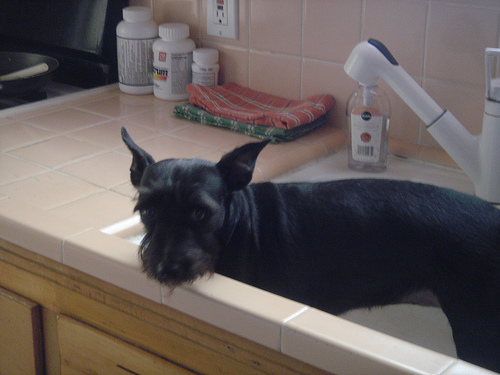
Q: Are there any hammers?
A: No, there are no hammers.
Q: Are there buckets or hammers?
A: No, there are no hammers or buckets.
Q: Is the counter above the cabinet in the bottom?
A: Yes, the counter is above the cabinet.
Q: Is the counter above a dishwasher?
A: No, the counter is above the cabinet.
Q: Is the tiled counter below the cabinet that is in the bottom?
A: No, the counter is above the cabinet.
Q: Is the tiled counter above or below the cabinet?
A: The counter is above the cabinet.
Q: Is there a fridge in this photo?
A: No, there are no refrigerators.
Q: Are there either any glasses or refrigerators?
A: No, there are no refrigerators or glasses.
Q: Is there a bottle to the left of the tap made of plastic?
A: Yes, there are bottles to the left of the faucet.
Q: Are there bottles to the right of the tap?
A: No, the bottles are to the left of the tap.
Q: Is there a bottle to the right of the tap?
A: No, the bottles are to the left of the tap.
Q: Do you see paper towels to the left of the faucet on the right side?
A: No, there are bottles to the left of the tap.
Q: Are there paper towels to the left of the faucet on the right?
A: No, there are bottles to the left of the tap.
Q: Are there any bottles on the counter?
A: Yes, there are bottles on the counter.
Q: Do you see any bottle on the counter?
A: Yes, there are bottles on the counter.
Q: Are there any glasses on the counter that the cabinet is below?
A: No, there are bottles on the counter.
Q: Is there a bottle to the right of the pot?
A: Yes, there are bottles to the right of the pot.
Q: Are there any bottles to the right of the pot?
A: Yes, there are bottles to the right of the pot.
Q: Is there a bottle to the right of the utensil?
A: Yes, there are bottles to the right of the utensil.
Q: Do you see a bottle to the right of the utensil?
A: Yes, there are bottles to the right of the utensil.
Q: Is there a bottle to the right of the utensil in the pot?
A: Yes, there are bottles to the right of the utensil.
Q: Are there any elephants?
A: No, there are no elephants.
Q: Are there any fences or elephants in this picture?
A: No, there are no elephants or fences.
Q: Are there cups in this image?
A: No, there are no cups.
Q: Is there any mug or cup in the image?
A: No, there are no cups or mugs.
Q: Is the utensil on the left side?
A: Yes, the utensil is on the left of the image.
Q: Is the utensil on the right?
A: No, the utensil is on the left of the image.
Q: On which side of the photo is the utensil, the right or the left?
A: The utensil is on the left of the image.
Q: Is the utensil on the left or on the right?
A: The utensil is on the left of the image.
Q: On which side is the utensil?
A: The utensil is on the left of the image.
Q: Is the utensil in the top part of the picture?
A: Yes, the utensil is in the top of the image.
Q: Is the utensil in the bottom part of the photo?
A: No, the utensil is in the top of the image.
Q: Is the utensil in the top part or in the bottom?
A: The utensil is in the top of the image.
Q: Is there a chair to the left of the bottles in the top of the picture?
A: No, there is a utensil to the left of the bottles.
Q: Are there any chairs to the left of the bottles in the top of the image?
A: No, there is a utensil to the left of the bottles.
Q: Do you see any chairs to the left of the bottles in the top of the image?
A: No, there is a utensil to the left of the bottles.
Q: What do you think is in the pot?
A: The utensil is in the pot.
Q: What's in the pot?
A: The utensil is in the pot.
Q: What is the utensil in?
A: The utensil is in the pot.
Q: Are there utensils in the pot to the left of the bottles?
A: Yes, there is a utensil in the pot.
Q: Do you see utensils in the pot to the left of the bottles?
A: Yes, there is a utensil in the pot.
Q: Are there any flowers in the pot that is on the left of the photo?
A: No, there is a utensil in the pot.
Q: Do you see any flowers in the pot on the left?
A: No, there is a utensil in the pot.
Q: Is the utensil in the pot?
A: Yes, the utensil is in the pot.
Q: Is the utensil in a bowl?
A: No, the utensil is in the pot.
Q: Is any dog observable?
A: Yes, there is a dog.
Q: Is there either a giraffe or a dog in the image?
A: Yes, there is a dog.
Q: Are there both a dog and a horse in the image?
A: No, there is a dog but no horses.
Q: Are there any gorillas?
A: No, there are no gorillas.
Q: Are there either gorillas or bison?
A: No, there are no gorillas or bison.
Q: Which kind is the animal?
A: The animal is a dog.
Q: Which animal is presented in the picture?
A: The animal is a dog.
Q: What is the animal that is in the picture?
A: The animal is a dog.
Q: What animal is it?
A: The animal is a dog.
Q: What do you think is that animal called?
A: This is a dog.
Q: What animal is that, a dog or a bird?
A: This is a dog.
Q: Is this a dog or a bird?
A: This is a dog.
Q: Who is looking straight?
A: The dog is looking straight.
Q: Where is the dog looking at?
A: The dog is looking straight.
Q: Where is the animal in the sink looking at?
A: The dog is looking straight.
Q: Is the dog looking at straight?
A: Yes, the dog is looking straight.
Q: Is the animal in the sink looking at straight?
A: Yes, the dog is looking straight.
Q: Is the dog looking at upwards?
A: No, the dog is looking straight.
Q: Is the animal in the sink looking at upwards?
A: No, the dog is looking straight.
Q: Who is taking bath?
A: The dog is taking bath.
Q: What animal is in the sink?
A: The dog is in the sink.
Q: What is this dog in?
A: The dog is in the sink.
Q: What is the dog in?
A: The dog is in the sink.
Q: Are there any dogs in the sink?
A: Yes, there is a dog in the sink.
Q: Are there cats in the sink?
A: No, there is a dog in the sink.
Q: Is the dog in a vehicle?
A: No, the dog is in the sink.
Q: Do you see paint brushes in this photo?
A: No, there are no paint brushes.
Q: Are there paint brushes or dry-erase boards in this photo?
A: No, there are no paint brushes or dry-erase boards.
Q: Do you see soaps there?
A: Yes, there is a soap.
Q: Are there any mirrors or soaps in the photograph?
A: Yes, there is a soap.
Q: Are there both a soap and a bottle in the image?
A: Yes, there are both a soap and a bottle.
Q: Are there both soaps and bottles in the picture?
A: Yes, there are both a soap and a bottle.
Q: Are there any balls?
A: No, there are no balls.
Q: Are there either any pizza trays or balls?
A: No, there are no balls or pizza trays.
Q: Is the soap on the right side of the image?
A: Yes, the soap is on the right of the image.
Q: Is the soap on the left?
A: No, the soap is on the right of the image.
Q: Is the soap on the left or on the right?
A: The soap is on the right of the image.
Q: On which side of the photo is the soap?
A: The soap is on the right of the image.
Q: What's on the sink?
A: The soap is on the sink.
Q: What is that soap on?
A: The soap is on the sink.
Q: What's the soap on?
A: The soap is on the sink.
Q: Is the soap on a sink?
A: Yes, the soap is on a sink.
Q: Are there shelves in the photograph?
A: No, there are no shelves.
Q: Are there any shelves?
A: No, there are no shelves.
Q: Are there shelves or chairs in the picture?
A: No, there are no shelves or chairs.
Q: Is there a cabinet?
A: Yes, there is a cabinet.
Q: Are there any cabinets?
A: Yes, there is a cabinet.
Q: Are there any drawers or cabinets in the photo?
A: Yes, there is a cabinet.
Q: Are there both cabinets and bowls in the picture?
A: No, there is a cabinet but no bowls.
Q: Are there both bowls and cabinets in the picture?
A: No, there is a cabinet but no bowls.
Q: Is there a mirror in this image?
A: No, there are no mirrors.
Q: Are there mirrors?
A: No, there are no mirrors.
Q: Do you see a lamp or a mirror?
A: No, there are no mirrors or lamps.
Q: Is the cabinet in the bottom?
A: Yes, the cabinet is in the bottom of the image.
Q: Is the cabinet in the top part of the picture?
A: No, the cabinet is in the bottom of the image.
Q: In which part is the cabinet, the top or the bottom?
A: The cabinet is in the bottom of the image.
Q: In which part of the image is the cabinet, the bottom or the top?
A: The cabinet is in the bottom of the image.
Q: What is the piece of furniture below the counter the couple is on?
A: The piece of furniture is a cabinet.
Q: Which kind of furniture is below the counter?
A: The piece of furniture is a cabinet.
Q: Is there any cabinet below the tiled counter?
A: Yes, there is a cabinet below the counter.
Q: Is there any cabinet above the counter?
A: No, the cabinet is below the counter.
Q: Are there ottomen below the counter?
A: No, there is a cabinet below the counter.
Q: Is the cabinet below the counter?
A: Yes, the cabinet is below the counter.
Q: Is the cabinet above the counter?
A: No, the cabinet is below the counter.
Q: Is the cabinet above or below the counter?
A: The cabinet is below the counter.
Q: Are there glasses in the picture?
A: No, there are no glasses.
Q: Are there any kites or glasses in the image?
A: No, there are no glasses or kites.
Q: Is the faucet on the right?
A: Yes, the faucet is on the right of the image.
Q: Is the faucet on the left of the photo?
A: No, the faucet is on the right of the image.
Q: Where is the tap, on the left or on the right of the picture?
A: The tap is on the right of the image.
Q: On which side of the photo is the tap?
A: The tap is on the right of the image.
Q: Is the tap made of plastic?
A: Yes, the tap is made of plastic.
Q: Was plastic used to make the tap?
A: Yes, the tap is made of plastic.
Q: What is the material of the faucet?
A: The faucet is made of plastic.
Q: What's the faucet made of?
A: The faucet is made of plastic.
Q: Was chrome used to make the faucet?
A: No, the faucet is made of plastic.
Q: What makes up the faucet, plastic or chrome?
A: The faucet is made of plastic.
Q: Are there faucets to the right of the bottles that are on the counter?
A: Yes, there is a faucet to the right of the bottles.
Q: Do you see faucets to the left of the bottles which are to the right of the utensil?
A: No, the faucet is to the right of the bottles.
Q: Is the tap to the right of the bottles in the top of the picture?
A: Yes, the tap is to the right of the bottles.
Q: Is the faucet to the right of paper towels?
A: No, the faucet is to the right of the bottles.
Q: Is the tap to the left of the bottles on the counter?
A: No, the tap is to the right of the bottles.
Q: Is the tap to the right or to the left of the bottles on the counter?
A: The tap is to the right of the bottles.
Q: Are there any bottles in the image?
A: Yes, there is a bottle.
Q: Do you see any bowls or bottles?
A: Yes, there is a bottle.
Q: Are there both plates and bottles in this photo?
A: No, there is a bottle but no plates.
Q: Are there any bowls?
A: No, there are no bowls.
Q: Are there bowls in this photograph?
A: No, there are no bowls.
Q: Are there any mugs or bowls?
A: No, there are no bowls or mugs.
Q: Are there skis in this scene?
A: No, there are no skis.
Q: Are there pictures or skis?
A: No, there are no skis or pictures.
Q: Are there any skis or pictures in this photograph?
A: No, there are no skis or pictures.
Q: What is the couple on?
A: The couple is on the counter.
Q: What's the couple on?
A: The couple is on the counter.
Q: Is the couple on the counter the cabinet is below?
A: Yes, the couple is on the counter.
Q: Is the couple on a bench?
A: No, the couple is on the counter.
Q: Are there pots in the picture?
A: Yes, there is a pot.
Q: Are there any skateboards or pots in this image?
A: Yes, there is a pot.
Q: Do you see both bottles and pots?
A: Yes, there are both a pot and a bottle.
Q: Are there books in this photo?
A: No, there are no books.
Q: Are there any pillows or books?
A: No, there are no books or pillows.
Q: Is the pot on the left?
A: Yes, the pot is on the left of the image.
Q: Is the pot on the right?
A: No, the pot is on the left of the image.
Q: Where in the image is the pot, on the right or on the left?
A: The pot is on the left of the image.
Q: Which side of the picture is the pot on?
A: The pot is on the left of the image.